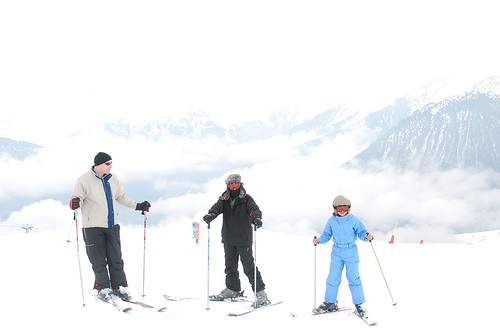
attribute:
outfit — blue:
[320, 212, 365, 304]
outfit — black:
[210, 189, 266, 291]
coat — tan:
[73, 170, 137, 228]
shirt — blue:
[100, 173, 115, 226]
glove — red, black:
[69, 197, 80, 209]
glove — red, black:
[136, 200, 150, 213]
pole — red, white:
[71, 207, 87, 307]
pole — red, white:
[141, 210, 150, 301]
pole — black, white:
[312, 237, 318, 311]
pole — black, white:
[366, 233, 396, 307]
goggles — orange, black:
[334, 204, 350, 213]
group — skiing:
[69, 152, 397, 327]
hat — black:
[93, 152, 111, 165]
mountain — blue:
[344, 75, 499, 177]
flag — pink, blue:
[192, 222, 200, 245]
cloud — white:
[207, 156, 495, 230]